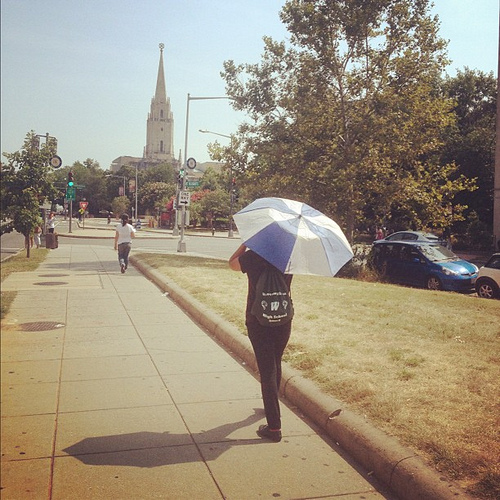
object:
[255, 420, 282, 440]
foot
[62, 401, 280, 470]
shadow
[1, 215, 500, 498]
ground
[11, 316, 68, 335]
manhole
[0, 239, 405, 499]
sidewalk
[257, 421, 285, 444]
shoe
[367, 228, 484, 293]
car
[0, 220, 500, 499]
street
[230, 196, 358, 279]
umbrella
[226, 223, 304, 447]
girl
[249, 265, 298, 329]
backpack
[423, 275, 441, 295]
tire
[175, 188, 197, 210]
sign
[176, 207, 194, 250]
post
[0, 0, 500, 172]
sky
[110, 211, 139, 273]
people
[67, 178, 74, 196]
signal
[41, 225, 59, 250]
disposal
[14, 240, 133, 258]
corner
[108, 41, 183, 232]
building